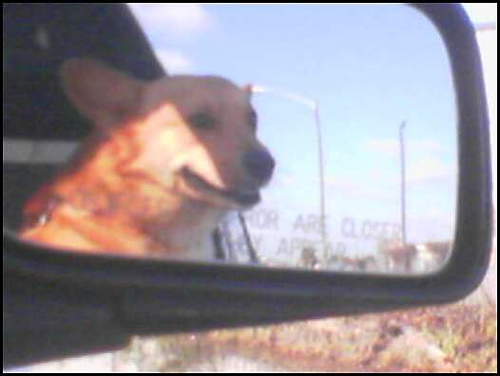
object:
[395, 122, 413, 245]
pole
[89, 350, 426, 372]
road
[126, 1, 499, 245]
sky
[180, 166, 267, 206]
mouth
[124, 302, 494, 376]
brown weeds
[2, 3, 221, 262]
window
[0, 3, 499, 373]
car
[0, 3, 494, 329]
mirror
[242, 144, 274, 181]
nose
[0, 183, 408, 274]
printed mirror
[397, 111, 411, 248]
light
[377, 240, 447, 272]
building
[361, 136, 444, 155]
cloud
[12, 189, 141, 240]
collar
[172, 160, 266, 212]
dog's mouth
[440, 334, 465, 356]
green weeds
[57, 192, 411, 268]
lettering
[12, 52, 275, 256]
dog is looking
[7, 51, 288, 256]
dog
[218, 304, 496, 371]
dry grass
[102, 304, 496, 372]
brown grass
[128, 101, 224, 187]
sunshine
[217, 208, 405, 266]
mirror sticker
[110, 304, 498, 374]
road grasses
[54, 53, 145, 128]
an ear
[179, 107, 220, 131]
an eye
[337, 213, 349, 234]
letter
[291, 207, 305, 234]
letter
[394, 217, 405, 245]
letter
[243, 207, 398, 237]
letter